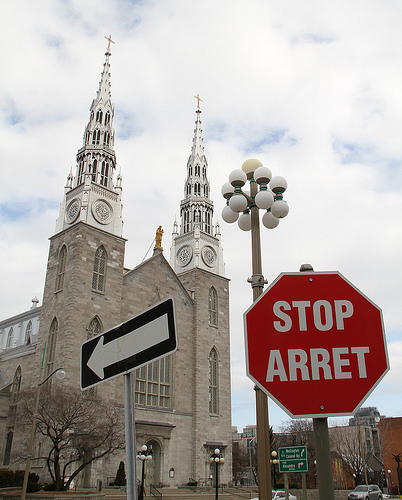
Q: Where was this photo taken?
A: A church.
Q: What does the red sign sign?
A: STOP ARRET.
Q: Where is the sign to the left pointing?
A: To the left.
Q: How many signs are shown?
A: Four.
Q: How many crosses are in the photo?
A: Two.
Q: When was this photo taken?
A: Day time.